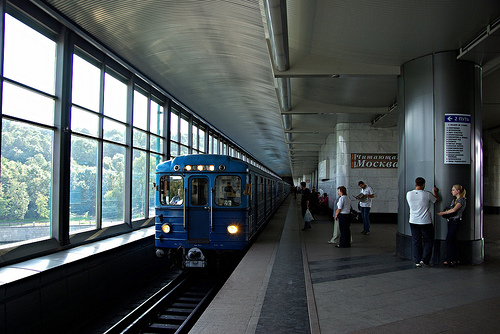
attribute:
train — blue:
[110, 89, 307, 275]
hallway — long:
[327, 67, 498, 320]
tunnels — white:
[258, 147, 344, 249]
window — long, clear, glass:
[2, 6, 286, 268]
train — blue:
[148, 150, 293, 273]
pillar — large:
[403, 60, 477, 268]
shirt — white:
[404, 190, 433, 226]